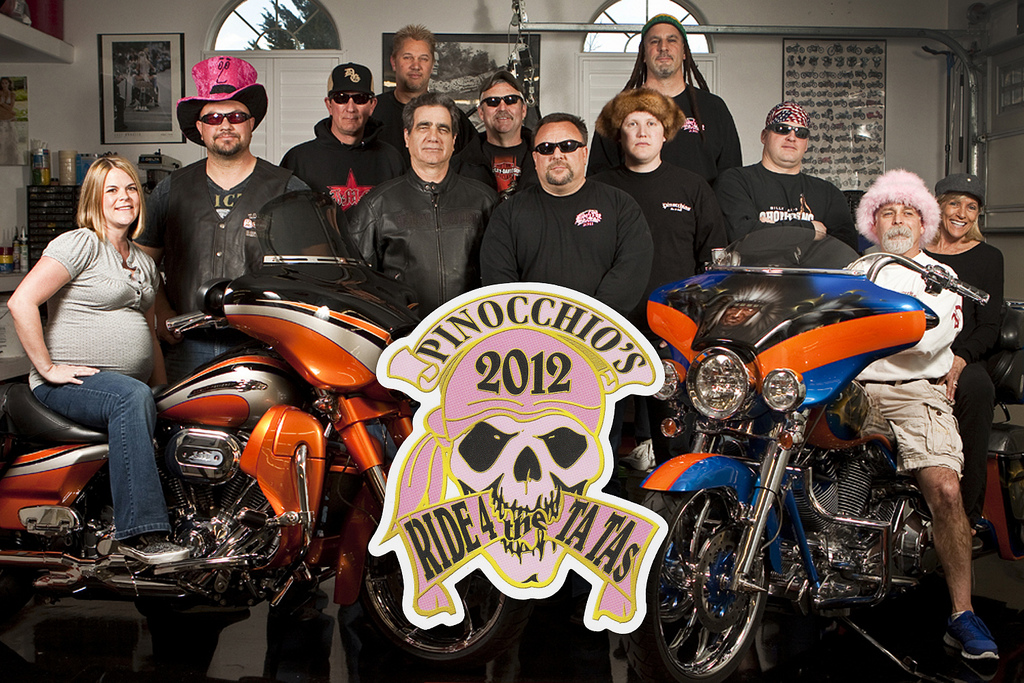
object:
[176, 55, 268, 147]
hat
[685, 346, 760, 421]
light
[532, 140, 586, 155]
sunglasses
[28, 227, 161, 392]
shirt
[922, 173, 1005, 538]
woman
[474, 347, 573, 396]
2012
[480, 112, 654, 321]
man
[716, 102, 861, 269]
man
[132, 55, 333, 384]
man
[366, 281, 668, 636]
skull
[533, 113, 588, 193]
face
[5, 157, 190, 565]
woman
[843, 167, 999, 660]
man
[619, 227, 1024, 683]
motorcycle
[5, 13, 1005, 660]
people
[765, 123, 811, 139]
sun glasses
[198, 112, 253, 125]
sun glasses